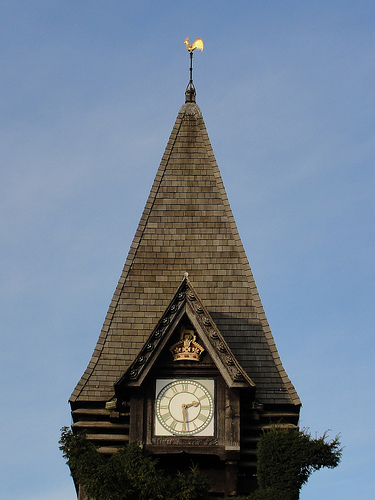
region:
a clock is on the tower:
[154, 371, 219, 441]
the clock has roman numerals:
[158, 382, 212, 435]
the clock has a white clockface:
[154, 378, 215, 436]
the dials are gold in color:
[181, 400, 199, 431]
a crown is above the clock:
[171, 330, 201, 361]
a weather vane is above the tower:
[183, 34, 203, 54]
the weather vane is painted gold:
[181, 34, 204, 53]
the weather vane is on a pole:
[186, 52, 193, 80]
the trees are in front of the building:
[58, 424, 343, 498]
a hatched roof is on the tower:
[71, 97, 303, 409]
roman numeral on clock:
[179, 380, 191, 396]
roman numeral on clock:
[190, 383, 201, 396]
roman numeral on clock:
[197, 392, 207, 403]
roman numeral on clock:
[196, 403, 212, 417]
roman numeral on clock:
[197, 409, 211, 424]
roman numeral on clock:
[188, 420, 200, 431]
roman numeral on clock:
[166, 418, 178, 430]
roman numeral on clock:
[156, 407, 172, 423]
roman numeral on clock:
[156, 402, 169, 412]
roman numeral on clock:
[160, 390, 176, 403]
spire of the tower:
[181, 24, 205, 82]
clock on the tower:
[152, 382, 215, 434]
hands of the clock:
[173, 398, 201, 424]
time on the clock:
[156, 378, 192, 397]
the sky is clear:
[1, 419, 47, 476]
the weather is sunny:
[310, 385, 353, 411]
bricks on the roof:
[137, 195, 224, 256]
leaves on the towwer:
[272, 431, 342, 477]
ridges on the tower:
[77, 403, 120, 438]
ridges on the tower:
[241, 404, 301, 429]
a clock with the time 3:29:
[152, 373, 218, 438]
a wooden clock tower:
[91, 28, 312, 496]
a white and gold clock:
[150, 370, 217, 437]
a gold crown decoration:
[166, 326, 208, 365]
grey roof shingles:
[88, 90, 302, 410]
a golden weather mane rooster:
[175, 31, 206, 59]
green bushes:
[47, 401, 336, 498]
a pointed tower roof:
[68, 90, 308, 412]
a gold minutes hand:
[178, 399, 191, 435]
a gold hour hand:
[188, 400, 200, 408]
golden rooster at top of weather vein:
[179, 34, 204, 52]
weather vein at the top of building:
[177, 34, 205, 105]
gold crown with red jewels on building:
[165, 326, 206, 366]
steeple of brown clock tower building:
[3, 8, 364, 481]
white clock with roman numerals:
[145, 378, 219, 443]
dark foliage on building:
[244, 425, 344, 488]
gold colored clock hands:
[179, 399, 198, 431]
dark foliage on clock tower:
[55, 428, 160, 494]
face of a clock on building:
[154, 374, 217, 441]